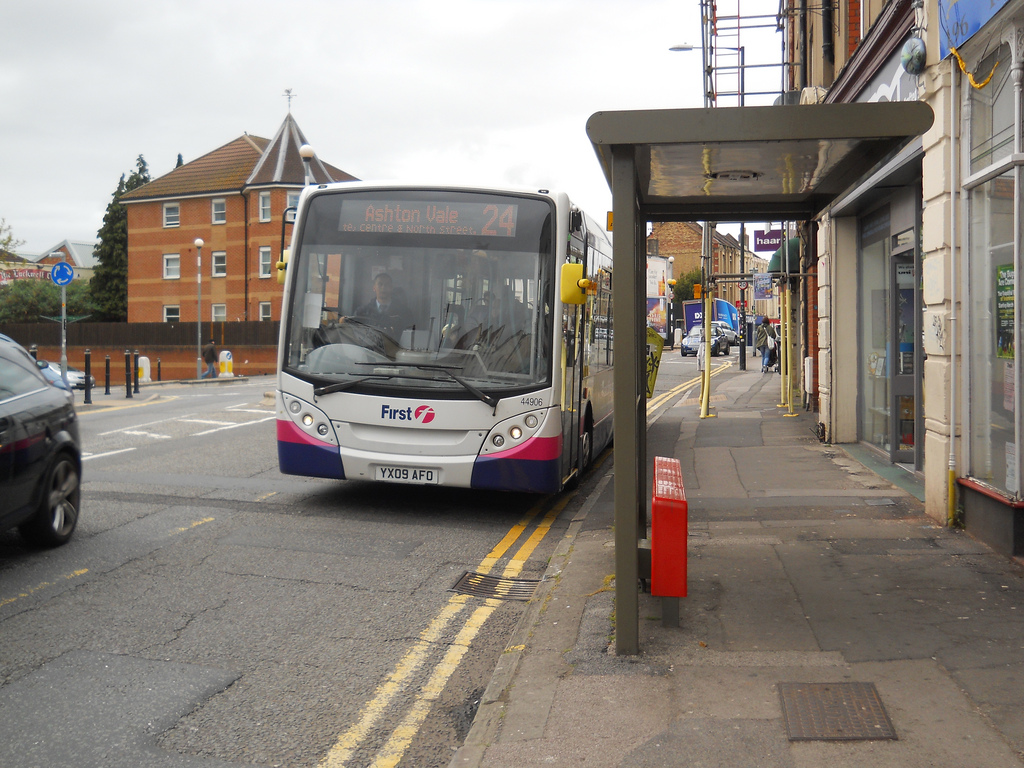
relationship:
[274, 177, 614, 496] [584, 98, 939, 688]
bus at a bus stop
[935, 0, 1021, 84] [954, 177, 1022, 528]
blue sign above door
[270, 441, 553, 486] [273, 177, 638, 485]
purple stripe on bus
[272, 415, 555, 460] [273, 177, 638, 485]
pink stripe on bus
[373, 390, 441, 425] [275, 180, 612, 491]
logo on bus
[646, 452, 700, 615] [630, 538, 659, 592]
red object attached to pole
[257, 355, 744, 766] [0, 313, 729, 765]
yellow lines on road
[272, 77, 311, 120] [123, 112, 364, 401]
weather vane on top of building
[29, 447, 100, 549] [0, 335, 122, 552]
tire of car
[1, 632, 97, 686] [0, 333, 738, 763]
crack in street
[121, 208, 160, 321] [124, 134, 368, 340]
wall on side of a building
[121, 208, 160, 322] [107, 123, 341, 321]
wall on side of a building